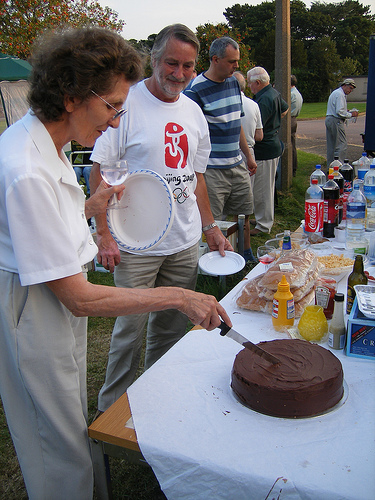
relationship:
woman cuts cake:
[1, 27, 234, 497] [231, 338, 348, 420]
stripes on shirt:
[194, 81, 240, 161] [187, 73, 244, 166]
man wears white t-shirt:
[90, 24, 230, 415] [89, 81, 210, 255]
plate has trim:
[103, 167, 175, 252] [105, 167, 174, 251]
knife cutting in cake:
[218, 319, 275, 365] [231, 338, 348, 420]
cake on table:
[231, 338, 348, 420] [85, 216, 371, 498]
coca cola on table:
[303, 178, 323, 244] [89, 147, 374, 462]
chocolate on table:
[229, 339, 343, 419] [85, 216, 371, 498]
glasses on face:
[91, 90, 128, 118] [68, 76, 131, 147]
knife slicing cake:
[218, 319, 275, 365] [231, 338, 348, 420]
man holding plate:
[90, 24, 230, 415] [199, 251, 245, 274]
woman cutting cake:
[1, 27, 234, 497] [231, 338, 348, 420]